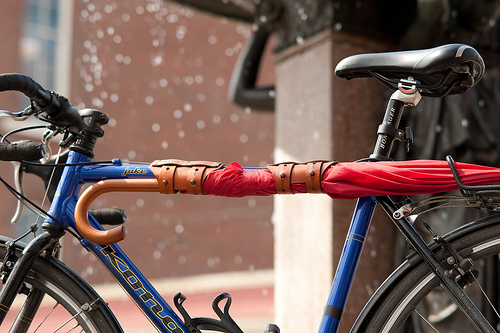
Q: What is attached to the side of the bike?
A: Umbrella.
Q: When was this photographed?
A: Daytime.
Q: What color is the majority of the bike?
A: Blue.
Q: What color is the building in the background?
A: Red.